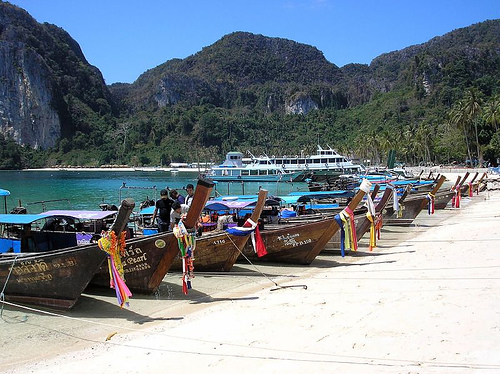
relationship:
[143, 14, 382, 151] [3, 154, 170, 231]
mountains near water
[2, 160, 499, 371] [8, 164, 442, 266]
sand near water